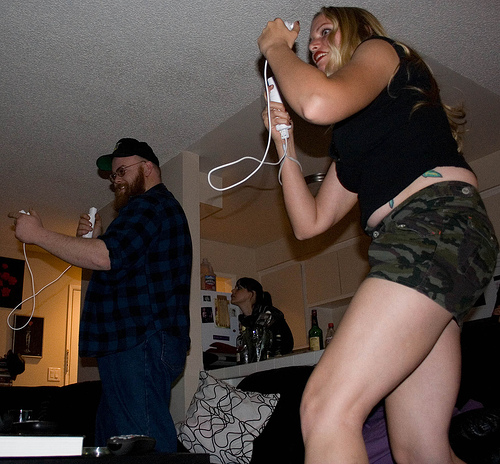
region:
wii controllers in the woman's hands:
[207, 20, 304, 182]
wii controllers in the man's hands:
[4, 202, 104, 332]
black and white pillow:
[175, 371, 285, 462]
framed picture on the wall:
[12, 311, 44, 361]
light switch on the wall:
[44, 365, 64, 381]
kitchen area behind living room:
[205, 162, 368, 366]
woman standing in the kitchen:
[227, 276, 293, 353]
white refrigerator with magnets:
[201, 287, 241, 358]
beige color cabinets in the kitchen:
[258, 264, 305, 349]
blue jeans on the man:
[95, 324, 190, 447]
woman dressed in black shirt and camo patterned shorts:
[261, 0, 494, 461]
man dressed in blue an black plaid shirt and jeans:
[10, 133, 197, 463]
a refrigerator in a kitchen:
[201, 286, 246, 366]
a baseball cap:
[93, 134, 163, 174]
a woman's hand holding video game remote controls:
[246, 15, 304, 142]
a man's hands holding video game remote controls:
[9, 203, 105, 245]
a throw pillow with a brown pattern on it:
[180, 373, 281, 462]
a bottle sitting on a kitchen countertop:
[305, 305, 326, 347]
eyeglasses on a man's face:
[100, 161, 145, 181]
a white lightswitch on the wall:
[43, 363, 64, 383]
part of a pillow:
[205, 413, 223, 415]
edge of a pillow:
[243, 390, 268, 399]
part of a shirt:
[108, 323, 125, 344]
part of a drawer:
[308, 278, 320, 293]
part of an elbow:
[301, 227, 316, 239]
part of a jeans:
[149, 388, 159, 400]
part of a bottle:
[313, 333, 321, 335]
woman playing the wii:
[259, 5, 491, 462]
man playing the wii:
[9, 134, 190, 459]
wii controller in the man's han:
[87, 199, 97, 240]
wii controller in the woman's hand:
[263, 73, 293, 139]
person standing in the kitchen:
[230, 277, 293, 356]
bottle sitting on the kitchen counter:
[305, 308, 322, 352]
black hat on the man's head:
[95, 135, 159, 174]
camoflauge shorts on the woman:
[369, 179, 493, 324]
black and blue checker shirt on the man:
[77, 195, 196, 350]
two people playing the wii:
[4, 9, 491, 454]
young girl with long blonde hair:
[296, 3, 473, 163]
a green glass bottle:
[302, 304, 324, 358]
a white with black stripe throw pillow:
[177, 368, 282, 462]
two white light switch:
[44, 363, 64, 383]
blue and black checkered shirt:
[78, 178, 203, 367]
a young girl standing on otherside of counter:
[207, 265, 329, 387]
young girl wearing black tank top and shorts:
[236, 7, 496, 381]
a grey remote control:
[105, 424, 159, 459]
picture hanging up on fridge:
[200, 289, 242, 350]